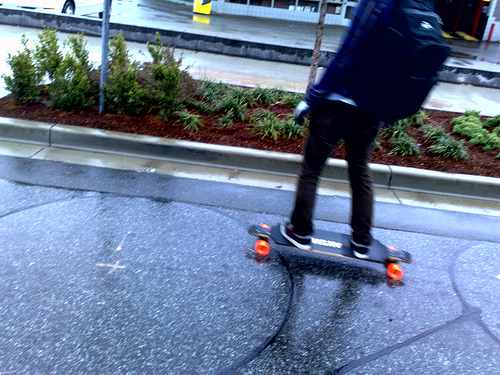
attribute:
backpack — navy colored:
[351, 0, 453, 129]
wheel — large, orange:
[386, 262, 405, 280]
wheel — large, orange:
[254, 238, 269, 255]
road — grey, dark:
[46, 193, 232, 364]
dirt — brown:
[6, 71, 499, 171]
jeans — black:
[293, 97, 384, 259]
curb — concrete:
[1, 115, 498, 200]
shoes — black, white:
[278, 221, 371, 261]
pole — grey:
[94, 2, 115, 114]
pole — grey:
[304, 0, 331, 87]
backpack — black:
[298, 3, 454, 130]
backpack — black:
[356, 2, 445, 115]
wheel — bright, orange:
[385, 262, 411, 283]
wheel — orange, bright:
[250, 236, 267, 258]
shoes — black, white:
[337, 246, 420, 288]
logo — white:
[397, 12, 455, 44]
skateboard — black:
[246, 218, 413, 283]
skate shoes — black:
[281, 220, 315, 251]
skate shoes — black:
[344, 239, 370, 261]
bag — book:
[353, 1, 453, 126]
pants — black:
[288, 94, 376, 245]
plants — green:
[4, 28, 287, 142]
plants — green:
[380, 107, 482, 148]